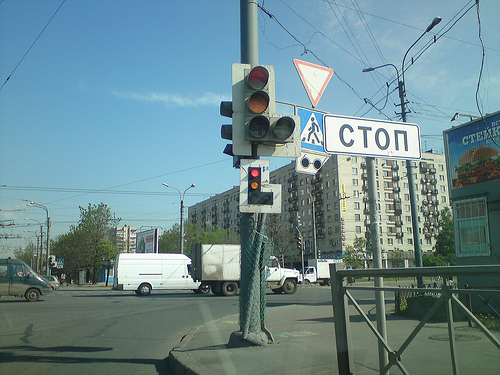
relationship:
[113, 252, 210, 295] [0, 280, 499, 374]
mini van on a ground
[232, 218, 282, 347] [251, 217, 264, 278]
fencing wrapped around pole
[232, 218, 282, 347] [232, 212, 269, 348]
fencing wrapped around pole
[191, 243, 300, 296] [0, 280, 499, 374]
truck crossing ground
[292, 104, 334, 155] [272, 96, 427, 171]
sign on post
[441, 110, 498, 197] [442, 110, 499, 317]
sign on wall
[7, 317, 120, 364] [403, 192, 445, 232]
shadows on ground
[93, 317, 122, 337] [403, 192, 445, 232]
stains on ground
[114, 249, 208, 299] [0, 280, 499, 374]
mini van on ground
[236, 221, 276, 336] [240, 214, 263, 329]
wire on pole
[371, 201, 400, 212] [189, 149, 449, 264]
balcony on building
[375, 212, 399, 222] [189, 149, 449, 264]
balcony on building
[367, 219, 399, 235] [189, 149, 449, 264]
balcony on building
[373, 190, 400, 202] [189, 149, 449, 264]
balcony on building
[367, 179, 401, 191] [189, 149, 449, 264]
balcony on building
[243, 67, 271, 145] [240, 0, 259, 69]
traffic light on pole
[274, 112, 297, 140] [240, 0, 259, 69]
traffic light on pole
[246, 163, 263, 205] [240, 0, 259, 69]
traffic light on pole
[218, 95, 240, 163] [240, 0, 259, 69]
traffic light on pole